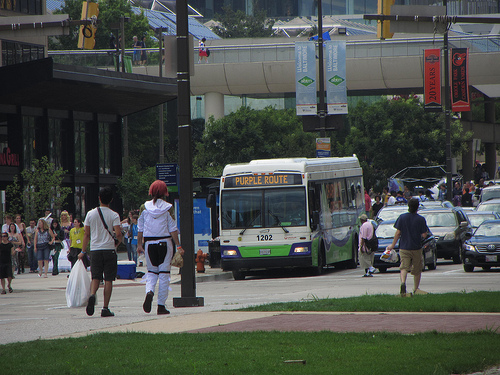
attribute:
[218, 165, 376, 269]
bus — green, blue, white, large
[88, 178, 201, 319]
couple — walking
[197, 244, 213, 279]
hydrant — red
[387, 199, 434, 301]
man — walking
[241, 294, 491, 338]
sidewalk — brick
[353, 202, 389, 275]
person — walking, crossing street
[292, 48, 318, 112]
banner — blue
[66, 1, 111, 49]
light — yellow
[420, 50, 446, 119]
banner — red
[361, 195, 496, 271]
cars — parked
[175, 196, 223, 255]
bus stand — white, blue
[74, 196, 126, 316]
man — walking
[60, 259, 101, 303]
bag — white, large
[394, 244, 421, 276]
shorts — tan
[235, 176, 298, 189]
sign — orange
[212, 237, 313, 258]
headlights — lit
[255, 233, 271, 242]
number — black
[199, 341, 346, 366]
grass — green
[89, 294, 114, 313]
shoes — black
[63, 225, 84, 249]
shirt — yellow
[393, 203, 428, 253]
shirt — blue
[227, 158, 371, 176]
bus roof — white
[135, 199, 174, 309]
clothes — white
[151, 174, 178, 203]
hat — red